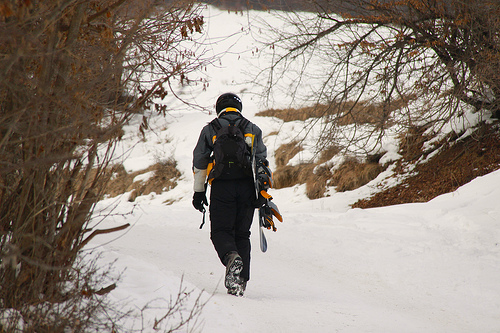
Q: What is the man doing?
A: Walking.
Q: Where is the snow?
A: On ground.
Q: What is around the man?
A: Snow.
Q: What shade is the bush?
A: Brown.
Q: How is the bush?
A: Dry.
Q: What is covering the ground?
A: Snow.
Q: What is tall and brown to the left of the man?
A: Trees.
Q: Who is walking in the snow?
A: A person.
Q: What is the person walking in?
A: Snow.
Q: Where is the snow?
A: On the ground.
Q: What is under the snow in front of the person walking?
A: Brown grass.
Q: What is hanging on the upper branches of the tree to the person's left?
A: Brown leaves.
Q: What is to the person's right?
A: Barren tree.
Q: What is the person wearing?
A: Snow suit.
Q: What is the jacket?
A: Gray.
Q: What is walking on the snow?
A: The single man.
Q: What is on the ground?
A: The snow.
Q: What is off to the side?
A: Some bare brown trees.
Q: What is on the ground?
A: Some more snow.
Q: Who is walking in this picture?
A: A man.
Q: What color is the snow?
A: White.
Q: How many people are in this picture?
A: One.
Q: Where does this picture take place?
A: On a snowy field.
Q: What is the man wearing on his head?
A: A helmet.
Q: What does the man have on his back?
A: A backpack.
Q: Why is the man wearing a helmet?
A: To protect his head in case of an accident.